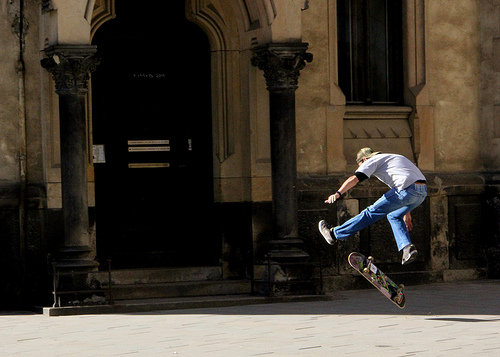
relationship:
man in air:
[318, 147, 427, 265] [25, 9, 467, 190]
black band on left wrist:
[336, 190, 342, 196] [335, 187, 343, 197]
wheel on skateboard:
[366, 256, 374, 261] [348, 249, 407, 306]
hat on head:
[357, 145, 379, 160] [349, 138, 379, 167]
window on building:
[333, 0, 415, 110] [3, 8, 484, 294]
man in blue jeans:
[318, 147, 427, 265] [333, 183, 428, 252]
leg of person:
[387, 192, 428, 247] [320, 115, 444, 278]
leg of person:
[333, 189, 414, 239] [317, 137, 462, 267]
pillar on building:
[250, 42, 314, 279] [3, 8, 484, 294]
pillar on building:
[64, 57, 99, 259] [3, 8, 484, 294]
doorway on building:
[83, 3, 230, 275] [3, 8, 484, 294]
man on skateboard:
[318, 147, 427, 265] [341, 245, 415, 315]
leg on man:
[387, 192, 428, 247] [319, 119, 444, 283]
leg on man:
[391, 210, 421, 263] [327, 138, 429, 258]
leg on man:
[387, 192, 428, 247] [318, 147, 427, 265]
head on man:
[348, 143, 383, 168] [301, 112, 433, 266]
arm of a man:
[323, 159, 375, 202] [318, 147, 427, 265]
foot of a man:
[318, 217, 337, 244] [318, 147, 427, 265]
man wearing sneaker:
[318, 147, 427, 265] [314, 217, 336, 243]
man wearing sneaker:
[318, 147, 427, 265] [397, 243, 419, 269]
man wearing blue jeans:
[318, 147, 427, 265] [331, 180, 430, 250]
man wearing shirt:
[318, 147, 427, 265] [356, 153, 438, 191]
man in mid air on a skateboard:
[318, 147, 427, 265] [347, 245, 407, 309]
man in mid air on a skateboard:
[318, 147, 427, 265] [348, 249, 407, 306]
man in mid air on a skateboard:
[318, 147, 427, 265] [344, 247, 411, 311]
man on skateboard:
[307, 142, 429, 309] [339, 239, 415, 314]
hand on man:
[324, 190, 342, 204] [318, 147, 427, 265]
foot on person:
[397, 242, 417, 265] [317, 142, 439, 267]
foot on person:
[318, 220, 337, 246] [317, 142, 439, 267]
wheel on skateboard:
[397, 281, 407, 290] [360, 235, 418, 330]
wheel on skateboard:
[392, 290, 403, 302] [360, 235, 418, 330]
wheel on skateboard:
[363, 268, 369, 274] [360, 235, 418, 330]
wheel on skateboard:
[367, 252, 377, 262] [360, 235, 418, 330]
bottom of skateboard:
[349, 248, 410, 306] [344, 247, 411, 311]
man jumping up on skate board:
[318, 147, 427, 265] [347, 250, 405, 305]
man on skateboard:
[318, 147, 427, 265] [348, 251, 411, 312]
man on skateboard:
[318, 147, 427, 265] [342, 246, 424, 300]